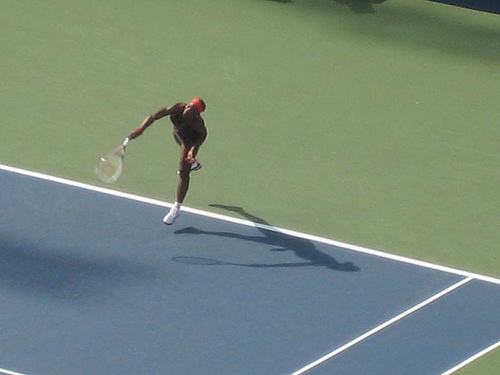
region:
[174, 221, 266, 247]
shadow of player's leg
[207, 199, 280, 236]
shadow of player's leg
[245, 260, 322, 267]
shadow of player's arm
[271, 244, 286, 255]
shadow of player's leg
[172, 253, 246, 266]
shadow of player's racket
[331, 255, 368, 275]
shadow of player's head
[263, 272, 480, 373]
white line on court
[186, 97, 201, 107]
orange headband on persons head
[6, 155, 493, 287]
white line on court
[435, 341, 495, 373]
white line on court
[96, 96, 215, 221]
Tennis player swinging a racket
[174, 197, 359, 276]
Shadow of a tennis player cast on the court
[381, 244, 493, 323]
Painted lines on a tennis court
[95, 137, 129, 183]
Racket of a tennis player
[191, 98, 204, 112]
Red band wrapped around someone's head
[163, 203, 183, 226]
White shoe in midair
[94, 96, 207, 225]
Tennis player in midair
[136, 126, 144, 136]
Wrist button on an arm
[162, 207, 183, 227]
white shoe of player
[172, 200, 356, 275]
black shadow on ground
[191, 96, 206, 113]
red headband on player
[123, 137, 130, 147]
white handle of racket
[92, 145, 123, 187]
racket swinging in the air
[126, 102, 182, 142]
dark arm of player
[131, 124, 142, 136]
orange wrist on player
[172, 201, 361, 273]
shadow of player on ground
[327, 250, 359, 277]
shadow of head on ground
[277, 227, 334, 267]
shadow of body on ground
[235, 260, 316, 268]
shadow of arm on ground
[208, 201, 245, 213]
shadow of shoe on ground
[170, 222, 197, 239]
shadow of shoe on ground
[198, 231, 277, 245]
shadow of leg on ground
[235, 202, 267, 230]
shadow of head on ground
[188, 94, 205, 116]
orange headband of player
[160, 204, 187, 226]
woman wearing white sneakers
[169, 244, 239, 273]
shadow of tennis racket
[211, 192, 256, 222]
shadow of left leg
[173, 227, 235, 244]
shadow of right leg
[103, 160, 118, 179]
inside of tennis racket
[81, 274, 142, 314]
blue paint on court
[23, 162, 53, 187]
white line on court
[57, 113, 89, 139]
green paint on court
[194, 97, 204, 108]
man wearing red headband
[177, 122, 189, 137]
woman wearing black shirt